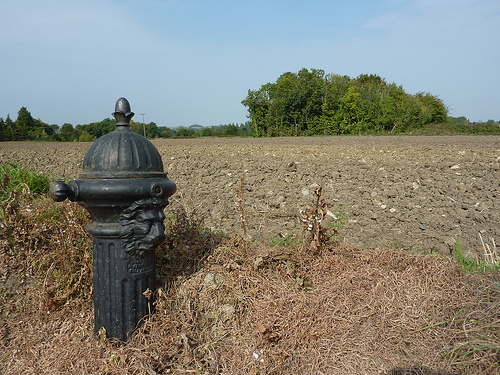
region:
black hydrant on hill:
[38, 121, 190, 363]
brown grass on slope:
[225, 261, 370, 366]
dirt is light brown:
[265, 136, 412, 243]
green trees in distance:
[249, 49, 481, 149]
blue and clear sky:
[280, 2, 469, 57]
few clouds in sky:
[277, 4, 410, 46]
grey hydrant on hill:
[63, 113, 195, 355]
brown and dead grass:
[24, 243, 115, 373]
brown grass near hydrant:
[154, 261, 307, 351]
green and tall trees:
[249, 73, 445, 139]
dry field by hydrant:
[268, 116, 425, 238]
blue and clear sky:
[222, 11, 321, 102]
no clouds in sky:
[193, 13, 323, 77]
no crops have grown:
[129, 130, 431, 262]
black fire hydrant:
[65, 89, 189, 327]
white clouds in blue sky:
[10, 8, 51, 53]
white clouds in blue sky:
[129, 41, 164, 85]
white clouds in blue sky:
[203, 69, 221, 91]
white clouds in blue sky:
[203, 13, 243, 55]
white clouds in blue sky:
[76, 53, 116, 73]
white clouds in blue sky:
[272, 16, 302, 56]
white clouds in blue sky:
[315, 23, 329, 51]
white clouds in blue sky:
[342, 8, 384, 52]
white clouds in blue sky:
[412, 33, 446, 60]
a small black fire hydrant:
[48, 95, 175, 351]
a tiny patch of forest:
[240, 65, 462, 135]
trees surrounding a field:
[0, 66, 495, 136]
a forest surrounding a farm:
[0, 70, 496, 166]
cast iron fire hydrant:
[50, 100, 176, 332]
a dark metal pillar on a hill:
[45, 98, 192, 343]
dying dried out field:
[170, 131, 495, 251]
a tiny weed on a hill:
[293, 178, 338, 262]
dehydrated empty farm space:
[3, 138, 494, 255]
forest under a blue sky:
[236, 37, 448, 134]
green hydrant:
[39, 88, 183, 339]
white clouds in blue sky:
[89, 31, 109, 51]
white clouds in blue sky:
[144, 51, 186, 78]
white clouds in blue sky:
[395, 28, 420, 48]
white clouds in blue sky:
[445, 48, 467, 76]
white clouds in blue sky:
[358, 20, 373, 36]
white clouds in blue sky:
[241, 40, 264, 52]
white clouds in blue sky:
[113, 8, 171, 48]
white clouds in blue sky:
[158, 55, 210, 90]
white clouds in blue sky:
[39, 38, 75, 74]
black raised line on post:
[108, 132, 123, 167]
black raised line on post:
[118, 133, 133, 169]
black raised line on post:
[130, 131, 147, 166]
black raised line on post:
[84, 134, 99, 161]